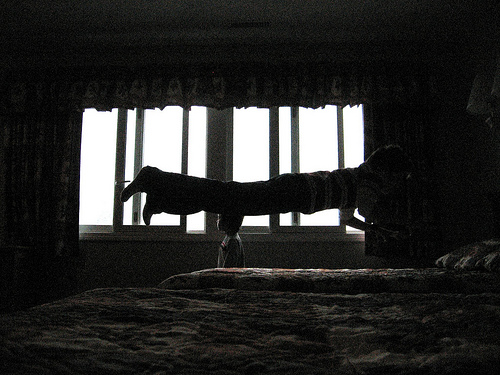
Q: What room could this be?
A: It is a bedroom.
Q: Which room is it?
A: It is a bedroom.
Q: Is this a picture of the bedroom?
A: Yes, it is showing the bedroom.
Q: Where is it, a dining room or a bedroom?
A: It is a bedroom.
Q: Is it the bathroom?
A: No, it is the bedroom.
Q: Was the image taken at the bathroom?
A: No, the picture was taken in the bedroom.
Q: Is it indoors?
A: Yes, it is indoors.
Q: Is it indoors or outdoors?
A: It is indoors.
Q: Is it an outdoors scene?
A: No, it is indoors.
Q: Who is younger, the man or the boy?
A: The boy is younger than the man.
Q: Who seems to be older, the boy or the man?
A: The man is older than the boy.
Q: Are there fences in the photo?
A: No, there are no fences.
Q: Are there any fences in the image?
A: No, there are no fences.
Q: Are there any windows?
A: Yes, there is a window.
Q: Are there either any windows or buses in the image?
A: Yes, there is a window.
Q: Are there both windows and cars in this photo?
A: No, there is a window but no cars.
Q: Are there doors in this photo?
A: No, there are no doors.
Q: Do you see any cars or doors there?
A: No, there are no doors or cars.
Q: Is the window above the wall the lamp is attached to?
A: Yes, the window is above the wall.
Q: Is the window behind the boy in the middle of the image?
A: Yes, the window is behind the boy.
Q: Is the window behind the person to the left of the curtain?
A: Yes, the window is behind the boy.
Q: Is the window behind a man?
A: Yes, the window is behind a man.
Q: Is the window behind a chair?
A: No, the window is behind a man.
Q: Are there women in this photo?
A: No, there are no women.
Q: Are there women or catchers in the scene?
A: No, there are no women or catchers.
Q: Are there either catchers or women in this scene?
A: No, there are no women or catchers.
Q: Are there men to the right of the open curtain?
A: Yes, there is a man to the right of the curtain.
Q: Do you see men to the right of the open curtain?
A: Yes, there is a man to the right of the curtain.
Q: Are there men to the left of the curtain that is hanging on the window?
A: No, the man is to the right of the curtain.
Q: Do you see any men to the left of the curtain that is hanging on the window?
A: No, the man is to the right of the curtain.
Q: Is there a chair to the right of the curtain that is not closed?
A: No, there is a man to the right of the curtain.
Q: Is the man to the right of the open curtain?
A: Yes, the man is to the right of the curtain.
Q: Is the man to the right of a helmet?
A: No, the man is to the right of the curtain.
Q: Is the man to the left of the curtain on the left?
A: No, the man is to the right of the curtain.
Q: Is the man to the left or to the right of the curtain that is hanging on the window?
A: The man is to the right of the curtain.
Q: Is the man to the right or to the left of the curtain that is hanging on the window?
A: The man is to the right of the curtain.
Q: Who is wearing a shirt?
A: The man is wearing a shirt.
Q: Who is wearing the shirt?
A: The man is wearing a shirt.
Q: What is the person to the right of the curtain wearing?
A: The man is wearing a shirt.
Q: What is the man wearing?
A: The man is wearing a shirt.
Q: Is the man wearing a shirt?
A: Yes, the man is wearing a shirt.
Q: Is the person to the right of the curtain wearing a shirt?
A: Yes, the man is wearing a shirt.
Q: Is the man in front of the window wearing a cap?
A: No, the man is wearing a shirt.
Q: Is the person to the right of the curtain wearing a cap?
A: No, the man is wearing a shirt.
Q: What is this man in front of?
A: The man is in front of the window.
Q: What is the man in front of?
A: The man is in front of the window.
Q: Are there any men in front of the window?
A: Yes, there is a man in front of the window.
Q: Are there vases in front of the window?
A: No, there is a man in front of the window.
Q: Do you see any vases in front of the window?
A: No, there is a man in front of the window.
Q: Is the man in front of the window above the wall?
A: Yes, the man is in front of the window.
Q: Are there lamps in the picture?
A: Yes, there is a lamp.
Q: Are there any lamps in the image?
A: Yes, there is a lamp.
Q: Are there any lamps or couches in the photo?
A: Yes, there is a lamp.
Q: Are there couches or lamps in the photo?
A: Yes, there is a lamp.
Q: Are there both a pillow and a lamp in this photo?
A: Yes, there are both a lamp and a pillow.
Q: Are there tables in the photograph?
A: No, there are no tables.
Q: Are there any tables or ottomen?
A: No, there are no tables or ottomen.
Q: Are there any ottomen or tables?
A: No, there are no tables or ottomen.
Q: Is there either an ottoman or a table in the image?
A: No, there are no tables or ottomen.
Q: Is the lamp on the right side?
A: Yes, the lamp is on the right of the image.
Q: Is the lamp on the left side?
A: No, the lamp is on the right of the image.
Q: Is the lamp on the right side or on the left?
A: The lamp is on the right of the image.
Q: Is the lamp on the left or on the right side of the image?
A: The lamp is on the right of the image.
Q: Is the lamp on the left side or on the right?
A: The lamp is on the right of the image.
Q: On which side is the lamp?
A: The lamp is on the right of the image.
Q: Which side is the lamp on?
A: The lamp is on the right of the image.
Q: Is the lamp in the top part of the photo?
A: Yes, the lamp is in the top of the image.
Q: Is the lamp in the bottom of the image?
A: No, the lamp is in the top of the image.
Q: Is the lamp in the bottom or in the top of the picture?
A: The lamp is in the top of the image.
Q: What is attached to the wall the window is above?
A: The lamp is attached to the wall.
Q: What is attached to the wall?
A: The lamp is attached to the wall.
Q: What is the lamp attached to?
A: The lamp is attached to the wall.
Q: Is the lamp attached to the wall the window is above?
A: Yes, the lamp is attached to the wall.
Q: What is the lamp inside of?
A: The lamp is inside the bedroom.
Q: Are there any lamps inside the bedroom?
A: Yes, there is a lamp inside the bedroom.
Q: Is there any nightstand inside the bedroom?
A: No, there is a lamp inside the bedroom.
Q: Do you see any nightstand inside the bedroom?
A: No, there is a lamp inside the bedroom.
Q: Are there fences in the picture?
A: No, there are no fences.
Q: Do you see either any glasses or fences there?
A: No, there are no fences or glasses.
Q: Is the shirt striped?
A: Yes, the shirt is striped.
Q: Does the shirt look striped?
A: Yes, the shirt is striped.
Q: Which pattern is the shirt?
A: The shirt is striped.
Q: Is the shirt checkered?
A: No, the shirt is striped.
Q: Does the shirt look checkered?
A: No, the shirt is striped.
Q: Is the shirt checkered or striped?
A: The shirt is striped.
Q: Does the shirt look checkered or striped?
A: The shirt is striped.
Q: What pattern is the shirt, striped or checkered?
A: The shirt is striped.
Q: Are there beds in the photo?
A: Yes, there is a bed.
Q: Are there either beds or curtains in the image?
A: Yes, there is a bed.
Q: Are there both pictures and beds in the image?
A: No, there is a bed but no pictures.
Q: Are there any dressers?
A: No, there are no dressers.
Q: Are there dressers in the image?
A: No, there are no dressers.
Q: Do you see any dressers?
A: No, there are no dressers.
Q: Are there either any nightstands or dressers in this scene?
A: No, there are no dressers or nightstands.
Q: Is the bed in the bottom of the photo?
A: Yes, the bed is in the bottom of the image.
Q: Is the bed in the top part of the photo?
A: No, the bed is in the bottom of the image.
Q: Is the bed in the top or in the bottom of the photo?
A: The bed is in the bottom of the image.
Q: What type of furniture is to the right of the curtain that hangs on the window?
A: The piece of furniture is a bed.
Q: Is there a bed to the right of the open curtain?
A: Yes, there is a bed to the right of the curtain.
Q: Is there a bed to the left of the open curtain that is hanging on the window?
A: No, the bed is to the right of the curtain.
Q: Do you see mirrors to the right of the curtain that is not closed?
A: No, there is a bed to the right of the curtain.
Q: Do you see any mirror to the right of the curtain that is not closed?
A: No, there is a bed to the right of the curtain.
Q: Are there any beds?
A: Yes, there is a bed.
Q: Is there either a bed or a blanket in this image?
A: Yes, there is a bed.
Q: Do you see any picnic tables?
A: No, there are no picnic tables.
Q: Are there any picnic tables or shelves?
A: No, there are no picnic tables or shelves.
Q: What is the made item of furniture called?
A: The piece of furniture is a bed.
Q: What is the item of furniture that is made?
A: The piece of furniture is a bed.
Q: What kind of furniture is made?
A: The furniture is a bed.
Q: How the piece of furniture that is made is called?
A: The piece of furniture is a bed.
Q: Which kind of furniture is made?
A: The furniture is a bed.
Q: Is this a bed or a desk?
A: This is a bed.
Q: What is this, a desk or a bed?
A: This is a bed.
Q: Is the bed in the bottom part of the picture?
A: Yes, the bed is in the bottom of the image.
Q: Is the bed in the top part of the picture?
A: No, the bed is in the bottom of the image.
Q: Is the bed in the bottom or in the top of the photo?
A: The bed is in the bottom of the image.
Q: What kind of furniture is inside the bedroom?
A: The piece of furniture is a bed.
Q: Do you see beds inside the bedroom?
A: Yes, there is a bed inside the bedroom.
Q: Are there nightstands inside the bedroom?
A: No, there is a bed inside the bedroom.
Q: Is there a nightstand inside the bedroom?
A: No, there is a bed inside the bedroom.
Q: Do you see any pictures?
A: No, there are no pictures.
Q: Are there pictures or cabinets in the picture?
A: No, there are no pictures or cabinets.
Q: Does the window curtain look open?
A: Yes, the curtain is open.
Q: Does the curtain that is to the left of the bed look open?
A: Yes, the curtain is open.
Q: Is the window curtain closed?
A: No, the curtain is open.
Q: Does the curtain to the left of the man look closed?
A: No, the curtain is open.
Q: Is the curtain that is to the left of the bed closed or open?
A: The curtain is open.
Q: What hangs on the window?
A: The curtain hangs on the window.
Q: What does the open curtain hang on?
A: The curtain hangs on the window.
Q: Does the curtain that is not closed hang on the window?
A: Yes, the curtain hangs on the window.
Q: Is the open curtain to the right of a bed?
A: No, the curtain is to the left of a bed.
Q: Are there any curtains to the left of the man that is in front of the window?
A: Yes, there is a curtain to the left of the man.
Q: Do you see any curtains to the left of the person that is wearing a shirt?
A: Yes, there is a curtain to the left of the man.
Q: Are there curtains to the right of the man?
A: No, the curtain is to the left of the man.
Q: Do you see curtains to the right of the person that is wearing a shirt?
A: No, the curtain is to the left of the man.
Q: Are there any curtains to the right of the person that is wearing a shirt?
A: No, the curtain is to the left of the man.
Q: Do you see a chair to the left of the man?
A: No, there is a curtain to the left of the man.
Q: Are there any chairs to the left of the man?
A: No, there is a curtain to the left of the man.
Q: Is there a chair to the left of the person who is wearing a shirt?
A: No, there is a curtain to the left of the man.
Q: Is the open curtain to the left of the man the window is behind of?
A: Yes, the curtain is to the left of the man.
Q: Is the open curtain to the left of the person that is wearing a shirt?
A: Yes, the curtain is to the left of the man.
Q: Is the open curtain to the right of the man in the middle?
A: No, the curtain is to the left of the man.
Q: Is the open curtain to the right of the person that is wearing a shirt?
A: No, the curtain is to the left of the man.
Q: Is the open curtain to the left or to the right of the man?
A: The curtain is to the left of the man.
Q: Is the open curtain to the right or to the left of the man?
A: The curtain is to the left of the man.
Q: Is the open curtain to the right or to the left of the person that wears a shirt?
A: The curtain is to the left of the man.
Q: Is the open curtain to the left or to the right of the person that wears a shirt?
A: The curtain is to the left of the man.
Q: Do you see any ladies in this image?
A: No, there are no ladies.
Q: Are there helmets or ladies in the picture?
A: No, there are no ladies or helmets.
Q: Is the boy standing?
A: Yes, the boy is standing.